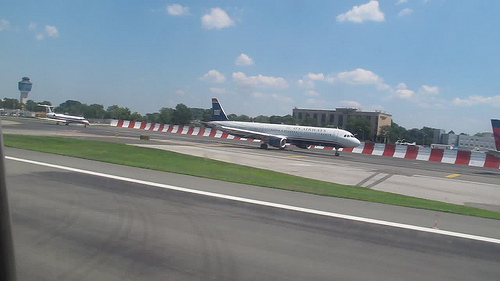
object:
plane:
[198, 97, 361, 156]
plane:
[37, 104, 90, 128]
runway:
[0, 120, 499, 278]